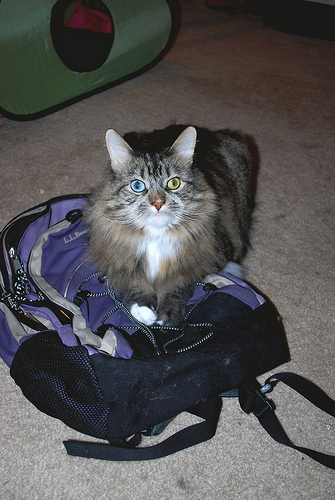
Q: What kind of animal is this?
A: House cat.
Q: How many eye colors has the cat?
A: Two.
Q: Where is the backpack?
A: On the floor.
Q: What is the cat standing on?
A: Backpack.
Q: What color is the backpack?
A: Purple and black.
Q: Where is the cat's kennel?
A: Behind it.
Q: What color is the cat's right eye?
A: Blue.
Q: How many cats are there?
A: One.